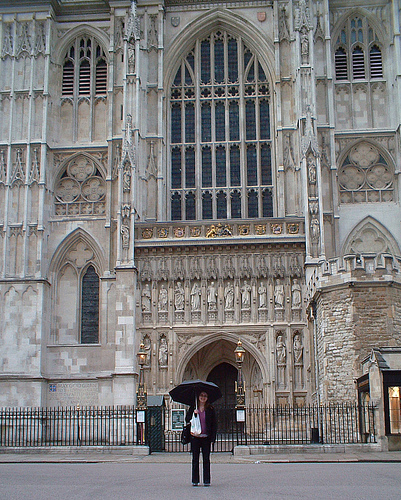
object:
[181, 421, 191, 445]
bag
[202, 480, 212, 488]
shoe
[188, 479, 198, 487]
shoe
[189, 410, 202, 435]
bag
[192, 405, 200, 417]
hand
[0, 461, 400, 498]
road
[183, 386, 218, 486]
woman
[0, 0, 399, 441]
building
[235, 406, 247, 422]
sign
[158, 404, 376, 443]
fence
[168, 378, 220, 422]
umbrella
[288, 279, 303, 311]
statues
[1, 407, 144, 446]
fence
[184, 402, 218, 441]
jacket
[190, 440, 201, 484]
legs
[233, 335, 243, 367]
lights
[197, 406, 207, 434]
shirt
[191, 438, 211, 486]
pants